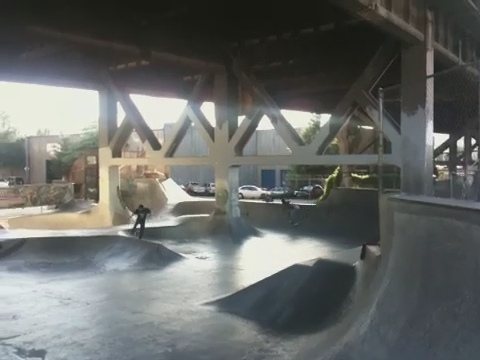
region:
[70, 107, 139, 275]
guy at a skate park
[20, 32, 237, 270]
guy at a skate park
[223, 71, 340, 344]
guy at a skate park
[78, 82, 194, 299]
guy at a skate park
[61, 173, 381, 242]
guy at a skate park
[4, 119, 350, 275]
guy at a skate park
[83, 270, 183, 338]
guy at a skate park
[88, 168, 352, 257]
people at a skate park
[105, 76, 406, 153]
beams at a skate park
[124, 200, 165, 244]
person in a skate park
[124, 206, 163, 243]
person in dark clothes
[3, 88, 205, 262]
sun shining at a skate park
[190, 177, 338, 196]
cars parked behind skate park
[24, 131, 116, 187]
building behind skaters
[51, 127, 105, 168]
trees in front of building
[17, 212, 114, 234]
brown grass near trees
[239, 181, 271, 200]
white parked car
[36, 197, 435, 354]
skate park under the structure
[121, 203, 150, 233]
the person is skateboarding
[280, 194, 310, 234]
the person is skateboarding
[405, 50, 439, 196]
the beam is white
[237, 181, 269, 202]
the car on the street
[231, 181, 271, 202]
the car is white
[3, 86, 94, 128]
the sky is sunny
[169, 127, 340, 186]
the building by the car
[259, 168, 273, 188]
the door on the building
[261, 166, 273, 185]
the door is blue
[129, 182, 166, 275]
There is a man who is skateboarding here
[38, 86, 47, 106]
There is a bright sky in the background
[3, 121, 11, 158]
There is a dark green tree here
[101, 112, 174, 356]
This photo really pops when you look at it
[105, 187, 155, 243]
boy is in ramp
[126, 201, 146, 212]
boy has dark hair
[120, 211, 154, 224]
boy has dark pants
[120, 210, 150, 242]
boy has dark shoes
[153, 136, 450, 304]
park is under bridge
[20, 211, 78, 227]
brown ground outside ramps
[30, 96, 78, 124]
white and grey sky